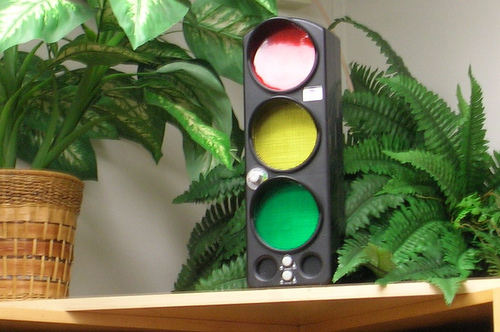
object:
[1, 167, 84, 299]
basket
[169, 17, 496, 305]
fern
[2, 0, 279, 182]
leaves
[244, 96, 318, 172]
sign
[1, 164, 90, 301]
pot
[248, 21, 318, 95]
red part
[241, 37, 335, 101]
reflection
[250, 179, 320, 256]
part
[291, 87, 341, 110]
sticker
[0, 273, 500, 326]
shelf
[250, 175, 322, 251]
sign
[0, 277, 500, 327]
table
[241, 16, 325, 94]
red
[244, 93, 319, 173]
yellow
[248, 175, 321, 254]
green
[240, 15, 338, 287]
light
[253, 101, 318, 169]
yellow plastic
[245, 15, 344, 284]
fake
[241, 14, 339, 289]
table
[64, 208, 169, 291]
wall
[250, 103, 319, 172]
lens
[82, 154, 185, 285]
shadow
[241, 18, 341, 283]
replica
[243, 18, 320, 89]
shade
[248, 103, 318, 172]
yellow part